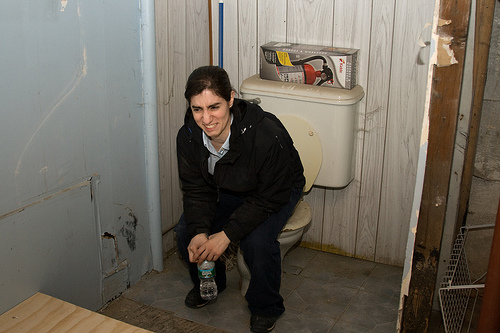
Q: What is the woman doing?
A: Peeing.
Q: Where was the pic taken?
A: In the toilet.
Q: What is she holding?
A: A bottle.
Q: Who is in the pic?
A: A lady.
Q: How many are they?
A: 1.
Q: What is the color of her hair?
A: Black.